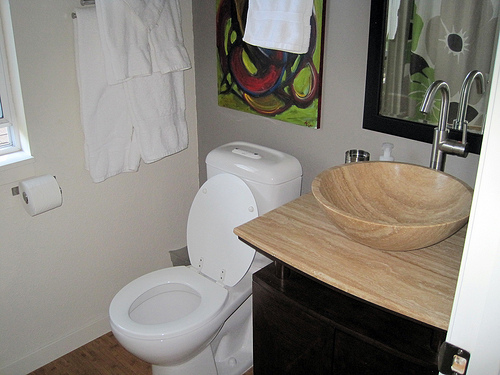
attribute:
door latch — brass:
[434, 339, 470, 373]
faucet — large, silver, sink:
[411, 76, 484, 175]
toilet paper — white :
[19, 172, 70, 220]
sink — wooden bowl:
[305, 141, 479, 278]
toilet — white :
[106, 137, 303, 370]